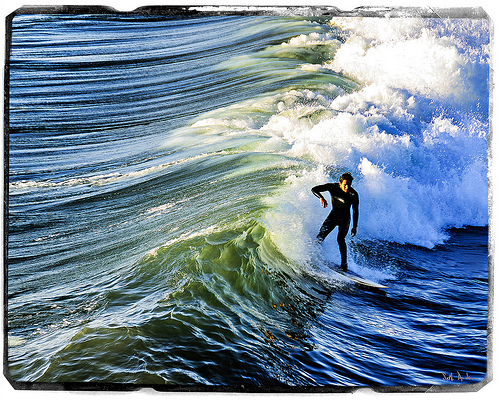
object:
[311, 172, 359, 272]
man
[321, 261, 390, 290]
surfboard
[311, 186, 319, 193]
elbow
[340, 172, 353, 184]
brown hair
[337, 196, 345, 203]
logo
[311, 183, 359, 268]
wetsuit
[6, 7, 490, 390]
waves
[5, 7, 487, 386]
ocean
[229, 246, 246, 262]
colors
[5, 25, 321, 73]
lines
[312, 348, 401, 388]
streaks